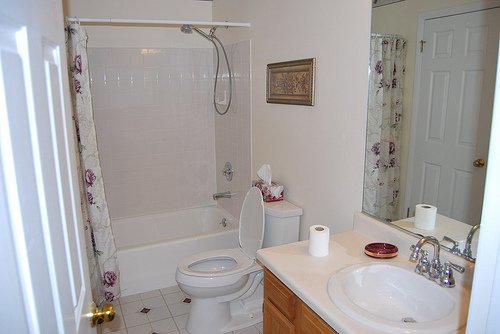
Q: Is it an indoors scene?
A: Yes, it is indoors.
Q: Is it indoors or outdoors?
A: It is indoors.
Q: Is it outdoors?
A: No, it is indoors.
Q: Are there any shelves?
A: No, there are no shelves.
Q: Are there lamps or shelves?
A: No, there are no shelves or lamps.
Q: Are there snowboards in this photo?
A: No, there are no snowboards.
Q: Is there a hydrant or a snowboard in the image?
A: No, there are no snowboards or fire hydrants.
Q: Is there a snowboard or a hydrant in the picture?
A: No, there are no snowboards or fire hydrants.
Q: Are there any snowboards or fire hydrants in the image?
A: No, there are no snowboards or fire hydrants.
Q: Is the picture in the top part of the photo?
A: Yes, the picture is in the top of the image.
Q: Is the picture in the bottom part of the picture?
A: No, the picture is in the top of the image.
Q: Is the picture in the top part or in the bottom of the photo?
A: The picture is in the top of the image.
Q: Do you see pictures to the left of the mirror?
A: Yes, there is a picture to the left of the mirror.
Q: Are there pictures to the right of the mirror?
A: No, the picture is to the left of the mirror.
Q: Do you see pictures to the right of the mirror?
A: No, the picture is to the left of the mirror.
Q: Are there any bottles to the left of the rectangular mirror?
A: No, there is a picture to the left of the mirror.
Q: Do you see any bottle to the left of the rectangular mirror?
A: No, there is a picture to the left of the mirror.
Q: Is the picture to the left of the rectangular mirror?
A: Yes, the picture is to the left of the mirror.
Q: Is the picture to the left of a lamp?
A: No, the picture is to the left of the mirror.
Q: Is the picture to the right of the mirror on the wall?
A: No, the picture is to the left of the mirror.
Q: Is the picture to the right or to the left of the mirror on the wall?
A: The picture is to the left of the mirror.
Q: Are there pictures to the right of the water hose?
A: Yes, there is a picture to the right of the water hose.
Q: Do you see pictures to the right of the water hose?
A: Yes, there is a picture to the right of the water hose.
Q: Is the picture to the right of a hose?
A: Yes, the picture is to the right of a hose.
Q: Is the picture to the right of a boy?
A: No, the picture is to the right of a hose.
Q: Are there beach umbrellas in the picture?
A: No, there are no beach umbrellas.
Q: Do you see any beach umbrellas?
A: No, there are no beach umbrellas.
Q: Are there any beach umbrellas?
A: No, there are no beach umbrellas.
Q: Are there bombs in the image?
A: No, there are no bombs.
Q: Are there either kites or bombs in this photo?
A: No, there are no bombs or kites.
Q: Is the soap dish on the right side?
A: Yes, the soap dish is on the right of the image.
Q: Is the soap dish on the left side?
A: No, the soap dish is on the right of the image.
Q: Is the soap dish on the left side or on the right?
A: The soap dish is on the right of the image.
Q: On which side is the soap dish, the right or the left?
A: The soap dish is on the right of the image.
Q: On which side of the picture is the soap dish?
A: The soap dish is on the right of the image.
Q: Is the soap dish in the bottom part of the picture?
A: Yes, the soap dish is in the bottom of the image.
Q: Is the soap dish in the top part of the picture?
A: No, the soap dish is in the bottom of the image.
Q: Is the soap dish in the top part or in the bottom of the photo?
A: The soap dish is in the bottom of the image.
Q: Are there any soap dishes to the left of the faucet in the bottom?
A: Yes, there is a soap dish to the left of the faucet.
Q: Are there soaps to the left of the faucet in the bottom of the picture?
A: No, there is a soap dish to the left of the faucet.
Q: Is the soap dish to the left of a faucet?
A: Yes, the soap dish is to the left of a faucet.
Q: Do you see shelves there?
A: No, there are no shelves.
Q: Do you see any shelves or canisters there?
A: No, there are no shelves or canisters.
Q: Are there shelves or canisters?
A: No, there are no shelves or canisters.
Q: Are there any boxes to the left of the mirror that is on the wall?
A: Yes, there is a box to the left of the mirror.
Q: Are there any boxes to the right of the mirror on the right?
A: No, the box is to the left of the mirror.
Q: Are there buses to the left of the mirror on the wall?
A: No, there is a box to the left of the mirror.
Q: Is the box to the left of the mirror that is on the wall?
A: Yes, the box is to the left of the mirror.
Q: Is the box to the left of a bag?
A: No, the box is to the left of the mirror.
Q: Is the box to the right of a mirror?
A: No, the box is to the left of a mirror.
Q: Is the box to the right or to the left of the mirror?
A: The box is to the left of the mirror.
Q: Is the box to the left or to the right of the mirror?
A: The box is to the left of the mirror.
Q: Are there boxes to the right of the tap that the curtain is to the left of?
A: Yes, there is a box to the right of the tap.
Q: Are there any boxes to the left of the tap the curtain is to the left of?
A: No, the box is to the right of the tap.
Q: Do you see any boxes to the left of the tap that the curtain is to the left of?
A: No, the box is to the right of the tap.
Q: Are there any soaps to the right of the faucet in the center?
A: No, there is a box to the right of the tap.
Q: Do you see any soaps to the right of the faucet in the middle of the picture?
A: No, there is a box to the right of the tap.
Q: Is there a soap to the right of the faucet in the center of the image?
A: No, there is a box to the right of the tap.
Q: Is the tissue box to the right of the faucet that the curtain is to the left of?
A: Yes, the box is to the right of the faucet.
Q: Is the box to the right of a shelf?
A: No, the box is to the right of the faucet.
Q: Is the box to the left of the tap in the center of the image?
A: No, the box is to the right of the faucet.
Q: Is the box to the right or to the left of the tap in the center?
A: The box is to the right of the faucet.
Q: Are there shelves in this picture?
A: No, there are no shelves.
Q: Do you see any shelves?
A: No, there are no shelves.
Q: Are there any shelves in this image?
A: No, there are no shelves.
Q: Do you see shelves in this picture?
A: No, there are no shelves.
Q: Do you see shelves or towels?
A: No, there are no shelves or towels.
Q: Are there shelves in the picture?
A: No, there are no shelves.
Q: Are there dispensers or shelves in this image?
A: No, there are no shelves or dispensers.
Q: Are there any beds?
A: No, there are no beds.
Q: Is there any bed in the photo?
A: No, there are no beds.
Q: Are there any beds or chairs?
A: No, there are no beds or chairs.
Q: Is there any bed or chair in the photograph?
A: No, there are no beds or chairs.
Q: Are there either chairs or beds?
A: No, there are no beds or chairs.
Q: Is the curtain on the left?
A: Yes, the curtain is on the left of the image.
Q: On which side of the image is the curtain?
A: The curtain is on the left of the image.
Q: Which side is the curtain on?
A: The curtain is on the left of the image.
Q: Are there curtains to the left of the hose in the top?
A: Yes, there is a curtain to the left of the hose.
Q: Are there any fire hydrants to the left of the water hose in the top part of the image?
A: No, there is a curtain to the left of the hose.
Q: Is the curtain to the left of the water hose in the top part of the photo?
A: Yes, the curtain is to the left of the water hose.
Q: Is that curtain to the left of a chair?
A: No, the curtain is to the left of the water hose.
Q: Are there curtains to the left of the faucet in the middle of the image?
A: Yes, there is a curtain to the left of the tap.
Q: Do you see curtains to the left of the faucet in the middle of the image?
A: Yes, there is a curtain to the left of the tap.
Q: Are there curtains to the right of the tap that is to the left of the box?
A: No, the curtain is to the left of the faucet.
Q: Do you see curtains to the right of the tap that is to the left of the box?
A: No, the curtain is to the left of the faucet.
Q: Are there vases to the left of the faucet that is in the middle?
A: No, there is a curtain to the left of the tap.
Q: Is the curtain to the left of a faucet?
A: Yes, the curtain is to the left of a faucet.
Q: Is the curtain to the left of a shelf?
A: No, the curtain is to the left of a faucet.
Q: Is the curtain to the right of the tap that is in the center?
A: No, the curtain is to the left of the tap.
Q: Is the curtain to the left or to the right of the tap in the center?
A: The curtain is to the left of the faucet.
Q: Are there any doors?
A: Yes, there is a door.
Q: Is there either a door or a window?
A: Yes, there is a door.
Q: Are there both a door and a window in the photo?
A: No, there is a door but no windows.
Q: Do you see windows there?
A: No, there are no windows.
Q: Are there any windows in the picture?
A: No, there are no windows.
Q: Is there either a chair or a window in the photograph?
A: No, there are no windows or chairs.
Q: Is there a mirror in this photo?
A: Yes, there is a mirror.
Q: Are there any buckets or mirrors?
A: Yes, there is a mirror.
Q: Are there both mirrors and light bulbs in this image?
A: No, there is a mirror but no light bulbs.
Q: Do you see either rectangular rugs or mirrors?
A: Yes, there is a rectangular mirror.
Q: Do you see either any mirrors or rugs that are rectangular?
A: Yes, the mirror is rectangular.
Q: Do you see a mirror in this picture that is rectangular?
A: Yes, there is a rectangular mirror.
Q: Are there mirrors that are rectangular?
A: Yes, there is a mirror that is rectangular.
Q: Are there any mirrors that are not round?
A: Yes, there is a rectangular mirror.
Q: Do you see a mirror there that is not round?
A: Yes, there is a rectangular mirror.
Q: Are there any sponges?
A: No, there are no sponges.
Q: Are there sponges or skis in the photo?
A: No, there are no sponges or skis.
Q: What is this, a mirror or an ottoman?
A: This is a mirror.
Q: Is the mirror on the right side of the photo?
A: Yes, the mirror is on the right of the image.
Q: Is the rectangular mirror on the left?
A: No, the mirror is on the right of the image.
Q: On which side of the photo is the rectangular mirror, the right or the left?
A: The mirror is on the right of the image.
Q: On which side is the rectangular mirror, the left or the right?
A: The mirror is on the right of the image.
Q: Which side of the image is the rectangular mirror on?
A: The mirror is on the right of the image.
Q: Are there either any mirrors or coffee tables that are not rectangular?
A: No, there is a mirror but it is rectangular.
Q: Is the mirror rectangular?
A: Yes, the mirror is rectangular.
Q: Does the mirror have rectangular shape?
A: Yes, the mirror is rectangular.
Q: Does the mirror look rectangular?
A: Yes, the mirror is rectangular.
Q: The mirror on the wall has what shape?
A: The mirror is rectangular.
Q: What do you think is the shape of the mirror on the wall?
A: The mirror is rectangular.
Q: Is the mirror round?
A: No, the mirror is rectangular.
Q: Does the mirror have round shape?
A: No, the mirror is rectangular.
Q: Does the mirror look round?
A: No, the mirror is rectangular.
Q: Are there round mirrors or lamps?
A: No, there is a mirror but it is rectangular.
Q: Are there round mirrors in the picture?
A: No, there is a mirror but it is rectangular.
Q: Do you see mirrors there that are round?
A: No, there is a mirror but it is rectangular.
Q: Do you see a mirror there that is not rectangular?
A: No, there is a mirror but it is rectangular.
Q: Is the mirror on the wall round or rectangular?
A: The mirror is rectangular.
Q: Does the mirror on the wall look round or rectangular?
A: The mirror is rectangular.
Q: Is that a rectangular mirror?
A: Yes, that is a rectangular mirror.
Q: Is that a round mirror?
A: No, that is a rectangular mirror.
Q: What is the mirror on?
A: The mirror is on the wall.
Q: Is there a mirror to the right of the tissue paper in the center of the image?
A: Yes, there is a mirror to the right of the tissue.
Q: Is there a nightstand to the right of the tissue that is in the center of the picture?
A: No, there is a mirror to the right of the tissue.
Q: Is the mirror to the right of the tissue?
A: Yes, the mirror is to the right of the tissue.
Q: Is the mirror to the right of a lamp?
A: No, the mirror is to the right of the tissue.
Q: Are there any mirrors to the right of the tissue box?
A: Yes, there is a mirror to the right of the box.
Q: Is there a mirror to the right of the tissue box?
A: Yes, there is a mirror to the right of the box.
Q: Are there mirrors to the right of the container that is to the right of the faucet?
A: Yes, there is a mirror to the right of the box.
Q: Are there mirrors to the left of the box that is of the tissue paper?
A: No, the mirror is to the right of the box.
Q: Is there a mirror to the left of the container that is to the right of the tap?
A: No, the mirror is to the right of the box.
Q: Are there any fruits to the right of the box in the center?
A: No, there is a mirror to the right of the box.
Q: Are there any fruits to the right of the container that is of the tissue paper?
A: No, there is a mirror to the right of the box.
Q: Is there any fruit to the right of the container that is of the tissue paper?
A: No, there is a mirror to the right of the box.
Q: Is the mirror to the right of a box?
A: Yes, the mirror is to the right of a box.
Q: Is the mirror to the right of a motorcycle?
A: No, the mirror is to the right of a box.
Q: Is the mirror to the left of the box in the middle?
A: No, the mirror is to the right of the box.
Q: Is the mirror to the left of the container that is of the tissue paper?
A: No, the mirror is to the right of the box.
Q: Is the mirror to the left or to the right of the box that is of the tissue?
A: The mirror is to the right of the box.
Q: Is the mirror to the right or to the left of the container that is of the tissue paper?
A: The mirror is to the right of the box.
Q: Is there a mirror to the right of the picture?
A: Yes, there is a mirror to the right of the picture.